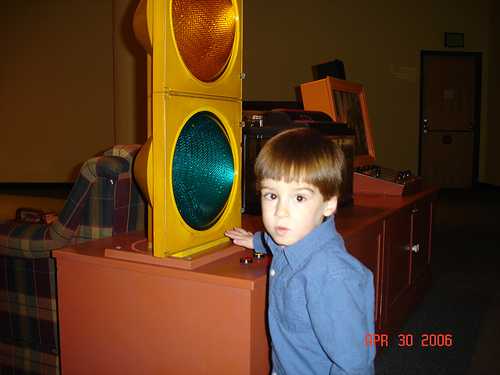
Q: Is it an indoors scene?
A: Yes, it is indoors.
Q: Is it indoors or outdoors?
A: It is indoors.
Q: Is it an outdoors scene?
A: No, it is indoors.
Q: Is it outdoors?
A: No, it is indoors.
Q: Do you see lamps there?
A: No, there are no lamps.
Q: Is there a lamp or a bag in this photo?
A: No, there are no lamps or bags.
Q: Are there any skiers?
A: No, there are no skiers.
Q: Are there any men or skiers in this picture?
A: No, there are no skiers or men.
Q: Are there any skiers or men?
A: No, there are no skiers or men.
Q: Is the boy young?
A: Yes, the boy is young.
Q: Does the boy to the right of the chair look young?
A: Yes, the boy is young.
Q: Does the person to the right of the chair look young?
A: Yes, the boy is young.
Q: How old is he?
A: The boy is young.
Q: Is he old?
A: No, the boy is young.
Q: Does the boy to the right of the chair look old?
A: No, the boy is young.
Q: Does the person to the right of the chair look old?
A: No, the boy is young.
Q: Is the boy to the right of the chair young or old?
A: The boy is young.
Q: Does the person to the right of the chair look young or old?
A: The boy is young.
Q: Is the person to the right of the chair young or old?
A: The boy is young.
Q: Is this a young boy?
A: Yes, this is a young boy.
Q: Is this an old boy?
A: No, this is a young boy.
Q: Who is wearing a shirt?
A: The boy is wearing a shirt.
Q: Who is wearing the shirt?
A: The boy is wearing a shirt.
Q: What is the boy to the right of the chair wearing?
A: The boy is wearing a shirt.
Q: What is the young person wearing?
A: The boy is wearing a shirt.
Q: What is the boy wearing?
A: The boy is wearing a shirt.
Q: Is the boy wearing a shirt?
A: Yes, the boy is wearing a shirt.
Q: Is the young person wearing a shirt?
A: Yes, the boy is wearing a shirt.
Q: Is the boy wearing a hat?
A: No, the boy is wearing a shirt.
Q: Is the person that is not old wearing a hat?
A: No, the boy is wearing a shirt.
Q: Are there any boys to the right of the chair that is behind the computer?
A: Yes, there is a boy to the right of the chair.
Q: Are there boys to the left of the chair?
A: No, the boy is to the right of the chair.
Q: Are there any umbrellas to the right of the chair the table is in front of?
A: No, there is a boy to the right of the chair.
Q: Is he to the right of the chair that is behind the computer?
A: Yes, the boy is to the right of the chair.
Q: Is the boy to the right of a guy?
A: No, the boy is to the right of the chair.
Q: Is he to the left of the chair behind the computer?
A: No, the boy is to the right of the chair.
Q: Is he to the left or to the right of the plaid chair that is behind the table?
A: The boy is to the right of the chair.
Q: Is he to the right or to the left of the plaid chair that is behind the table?
A: The boy is to the right of the chair.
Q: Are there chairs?
A: Yes, there is a chair.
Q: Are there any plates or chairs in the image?
A: Yes, there is a chair.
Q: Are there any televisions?
A: No, there are no televisions.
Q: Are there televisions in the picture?
A: No, there are no televisions.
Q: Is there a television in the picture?
A: No, there are no televisions.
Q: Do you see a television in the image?
A: No, there are no televisions.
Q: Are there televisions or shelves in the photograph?
A: No, there are no televisions or shelves.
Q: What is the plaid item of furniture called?
A: The piece of furniture is a chair.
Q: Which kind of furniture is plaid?
A: The furniture is a chair.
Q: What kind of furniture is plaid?
A: The furniture is a chair.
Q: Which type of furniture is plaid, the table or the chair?
A: The chair is plaid.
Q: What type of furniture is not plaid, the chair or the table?
A: The table is not plaid.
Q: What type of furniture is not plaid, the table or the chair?
A: The table is not plaid.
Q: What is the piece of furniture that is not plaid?
A: The piece of furniture is a table.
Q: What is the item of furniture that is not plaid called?
A: The piece of furniture is a table.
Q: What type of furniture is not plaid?
A: The furniture is a table.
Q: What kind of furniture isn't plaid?
A: The furniture is a table.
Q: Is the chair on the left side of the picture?
A: Yes, the chair is on the left of the image.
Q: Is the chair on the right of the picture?
A: No, the chair is on the left of the image.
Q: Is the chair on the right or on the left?
A: The chair is on the left of the image.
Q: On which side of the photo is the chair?
A: The chair is on the left of the image.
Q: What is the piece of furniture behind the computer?
A: The piece of furniture is a chair.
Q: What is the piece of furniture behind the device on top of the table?
A: The piece of furniture is a chair.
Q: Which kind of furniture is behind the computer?
A: The piece of furniture is a chair.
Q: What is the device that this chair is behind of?
A: The device is a computer.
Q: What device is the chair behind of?
A: The chair is behind the computer.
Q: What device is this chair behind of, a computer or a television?
A: The chair is behind a computer.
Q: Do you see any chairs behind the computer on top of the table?
A: Yes, there is a chair behind the computer.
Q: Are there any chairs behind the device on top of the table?
A: Yes, there is a chair behind the computer.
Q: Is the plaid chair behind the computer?
A: Yes, the chair is behind the computer.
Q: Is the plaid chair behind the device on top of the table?
A: Yes, the chair is behind the computer.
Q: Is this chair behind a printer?
A: No, the chair is behind the computer.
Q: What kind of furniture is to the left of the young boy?
A: The piece of furniture is a chair.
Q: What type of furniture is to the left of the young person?
A: The piece of furniture is a chair.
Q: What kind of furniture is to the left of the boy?
A: The piece of furniture is a chair.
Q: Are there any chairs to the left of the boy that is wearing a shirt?
A: Yes, there is a chair to the left of the boy.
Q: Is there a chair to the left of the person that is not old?
A: Yes, there is a chair to the left of the boy.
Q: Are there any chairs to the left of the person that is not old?
A: Yes, there is a chair to the left of the boy.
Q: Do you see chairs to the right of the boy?
A: No, the chair is to the left of the boy.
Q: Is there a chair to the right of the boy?
A: No, the chair is to the left of the boy.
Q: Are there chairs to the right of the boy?
A: No, the chair is to the left of the boy.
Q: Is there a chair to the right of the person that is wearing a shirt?
A: No, the chair is to the left of the boy.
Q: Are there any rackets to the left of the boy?
A: No, there is a chair to the left of the boy.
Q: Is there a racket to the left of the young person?
A: No, there is a chair to the left of the boy.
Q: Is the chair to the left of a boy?
A: Yes, the chair is to the left of a boy.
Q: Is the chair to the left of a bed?
A: No, the chair is to the left of a boy.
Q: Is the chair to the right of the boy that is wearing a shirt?
A: No, the chair is to the left of the boy.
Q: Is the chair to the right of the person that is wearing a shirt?
A: No, the chair is to the left of the boy.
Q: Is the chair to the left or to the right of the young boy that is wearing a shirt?
A: The chair is to the left of the boy.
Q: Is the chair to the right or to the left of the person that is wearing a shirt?
A: The chair is to the left of the boy.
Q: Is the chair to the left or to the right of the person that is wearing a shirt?
A: The chair is to the left of the boy.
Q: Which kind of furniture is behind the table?
A: The piece of furniture is a chair.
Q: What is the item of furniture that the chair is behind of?
A: The piece of furniture is a table.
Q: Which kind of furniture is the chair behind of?
A: The chair is behind the table.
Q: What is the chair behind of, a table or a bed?
A: The chair is behind a table.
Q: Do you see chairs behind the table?
A: Yes, there is a chair behind the table.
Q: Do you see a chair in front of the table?
A: No, the chair is behind the table.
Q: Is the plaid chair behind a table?
A: Yes, the chair is behind a table.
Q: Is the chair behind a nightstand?
A: No, the chair is behind a table.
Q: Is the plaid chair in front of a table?
A: No, the chair is behind a table.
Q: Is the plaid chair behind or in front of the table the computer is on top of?
A: The chair is behind the table.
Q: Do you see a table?
A: Yes, there is a table.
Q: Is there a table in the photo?
A: Yes, there is a table.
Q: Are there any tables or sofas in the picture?
A: Yes, there is a table.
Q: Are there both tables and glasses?
A: No, there is a table but no glasses.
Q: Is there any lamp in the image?
A: No, there are no lamps.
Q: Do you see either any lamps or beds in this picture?
A: No, there are no lamps or beds.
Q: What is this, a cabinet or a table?
A: This is a table.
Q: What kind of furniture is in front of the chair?
A: The piece of furniture is a table.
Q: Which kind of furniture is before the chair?
A: The piece of furniture is a table.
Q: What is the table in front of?
A: The table is in front of the chair.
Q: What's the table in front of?
A: The table is in front of the chair.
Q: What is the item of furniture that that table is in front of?
A: The piece of furniture is a chair.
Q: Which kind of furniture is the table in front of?
A: The table is in front of the chair.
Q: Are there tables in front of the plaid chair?
A: Yes, there is a table in front of the chair.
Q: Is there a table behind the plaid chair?
A: No, the table is in front of the chair.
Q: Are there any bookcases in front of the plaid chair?
A: No, there is a table in front of the chair.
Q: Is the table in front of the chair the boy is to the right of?
A: Yes, the table is in front of the chair.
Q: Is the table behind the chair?
A: No, the table is in front of the chair.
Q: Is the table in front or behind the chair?
A: The table is in front of the chair.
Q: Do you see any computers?
A: Yes, there is a computer.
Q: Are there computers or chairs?
A: Yes, there is a computer.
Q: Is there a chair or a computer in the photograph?
A: Yes, there is a computer.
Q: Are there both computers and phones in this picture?
A: No, there is a computer but no phones.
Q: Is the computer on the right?
A: Yes, the computer is on the right of the image.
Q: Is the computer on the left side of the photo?
A: No, the computer is on the right of the image.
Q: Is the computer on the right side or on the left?
A: The computer is on the right of the image.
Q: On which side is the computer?
A: The computer is on the right of the image.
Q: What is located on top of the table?
A: The computer is on top of the table.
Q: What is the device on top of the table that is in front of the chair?
A: The device is a computer.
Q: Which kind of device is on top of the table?
A: The device is a computer.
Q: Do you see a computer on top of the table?
A: Yes, there is a computer on top of the table.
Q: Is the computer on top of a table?
A: Yes, the computer is on top of a table.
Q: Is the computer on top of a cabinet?
A: No, the computer is on top of a table.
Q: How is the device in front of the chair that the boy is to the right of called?
A: The device is a computer.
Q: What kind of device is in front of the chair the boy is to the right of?
A: The device is a computer.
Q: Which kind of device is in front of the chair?
A: The device is a computer.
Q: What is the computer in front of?
A: The computer is in front of the chair.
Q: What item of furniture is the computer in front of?
A: The computer is in front of the chair.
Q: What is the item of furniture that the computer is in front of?
A: The piece of furniture is a chair.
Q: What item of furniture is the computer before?
A: The computer is in front of the chair.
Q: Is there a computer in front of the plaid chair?
A: Yes, there is a computer in front of the chair.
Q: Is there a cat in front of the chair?
A: No, there is a computer in front of the chair.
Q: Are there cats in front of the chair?
A: No, there is a computer in front of the chair.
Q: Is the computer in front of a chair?
A: Yes, the computer is in front of a chair.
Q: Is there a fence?
A: No, there are no fences.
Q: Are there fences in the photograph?
A: No, there are no fences.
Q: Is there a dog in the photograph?
A: No, there are no dogs.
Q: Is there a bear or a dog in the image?
A: No, there are no dogs or bears.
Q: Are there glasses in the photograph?
A: No, there are no glasses.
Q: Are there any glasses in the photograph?
A: No, there are no glasses.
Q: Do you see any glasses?
A: No, there are no glasses.